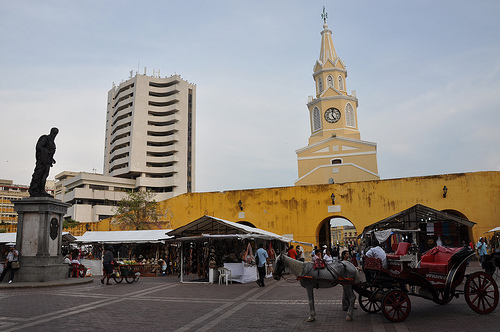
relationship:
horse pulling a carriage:
[271, 254, 362, 322] [357, 237, 499, 322]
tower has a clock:
[305, 5, 362, 143] [322, 107, 342, 123]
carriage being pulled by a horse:
[357, 237, 499, 322] [271, 254, 362, 322]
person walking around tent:
[254, 241, 273, 285] [75, 214, 317, 285]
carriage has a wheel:
[357, 237, 499, 322] [381, 288, 412, 322]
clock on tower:
[322, 107, 342, 123] [305, 5, 362, 143]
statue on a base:
[30, 125, 59, 196] [11, 196, 70, 279]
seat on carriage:
[418, 243, 457, 273] [357, 237, 499, 322]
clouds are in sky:
[360, 76, 500, 143] [1, 0, 500, 191]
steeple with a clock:
[320, 5, 330, 30] [322, 107, 342, 123]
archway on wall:
[310, 215, 362, 256] [61, 172, 499, 267]